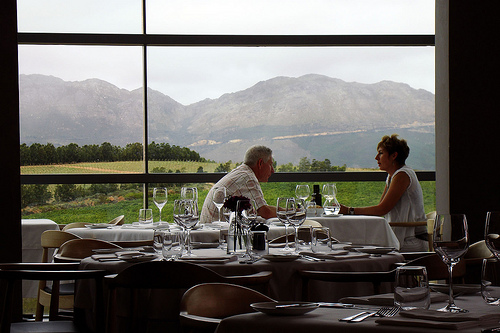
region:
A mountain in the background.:
[21, 70, 431, 145]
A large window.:
[5, 0, 455, 225]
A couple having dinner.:
[205, 130, 426, 251]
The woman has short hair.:
[327, 127, 432, 252]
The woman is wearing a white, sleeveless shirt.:
[350, 130, 437, 255]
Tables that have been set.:
[77, 195, 494, 325]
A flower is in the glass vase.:
[220, 192, 255, 254]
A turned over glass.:
[391, 265, 431, 310]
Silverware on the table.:
[320, 300, 400, 330]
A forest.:
[23, 135, 208, 170]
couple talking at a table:
[200, 126, 443, 243]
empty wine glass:
[421, 204, 480, 327]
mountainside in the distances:
[22, 52, 432, 143]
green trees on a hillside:
[24, 136, 212, 171]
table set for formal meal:
[81, 196, 432, 301]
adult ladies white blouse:
[387, 168, 434, 244]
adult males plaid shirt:
[192, 160, 274, 229]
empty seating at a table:
[41, 227, 127, 327]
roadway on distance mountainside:
[181, 116, 438, 149]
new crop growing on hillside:
[22, 154, 227, 172]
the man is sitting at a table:
[200, 144, 286, 229]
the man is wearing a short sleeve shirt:
[198, 163, 270, 224]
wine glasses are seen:
[151, 183, 351, 260]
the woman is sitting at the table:
[333, 137, 432, 247]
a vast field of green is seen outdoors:
[21, 134, 443, 236]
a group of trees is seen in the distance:
[21, 136, 210, 171]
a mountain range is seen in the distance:
[21, 65, 439, 147]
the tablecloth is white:
[21, 216, 61, 313]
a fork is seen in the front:
[341, 306, 405, 326]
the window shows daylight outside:
[16, 1, 442, 319]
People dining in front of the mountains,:
[148, 115, 432, 272]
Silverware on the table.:
[316, 266, 377, 329]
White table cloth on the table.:
[98, 218, 383, 243]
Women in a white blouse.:
[374, 122, 476, 297]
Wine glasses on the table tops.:
[113, 180, 292, 292]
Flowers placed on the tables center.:
[218, 184, 275, 272]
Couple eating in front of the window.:
[150, 105, 403, 241]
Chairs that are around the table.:
[150, 262, 221, 317]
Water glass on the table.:
[386, 248, 462, 328]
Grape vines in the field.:
[93, 130, 231, 212]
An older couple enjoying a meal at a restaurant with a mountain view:
[196, 120, 433, 244]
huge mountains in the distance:
[23, 62, 435, 148]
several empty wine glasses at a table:
[149, 183, 234, 225]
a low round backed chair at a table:
[181, 278, 284, 328]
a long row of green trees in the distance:
[20, 133, 205, 175]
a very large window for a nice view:
[14, 3, 441, 218]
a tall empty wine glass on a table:
[428, 206, 473, 318]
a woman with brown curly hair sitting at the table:
[354, 132, 429, 229]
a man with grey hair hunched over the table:
[196, 141, 286, 226]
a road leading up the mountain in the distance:
[274, 122, 436, 146]